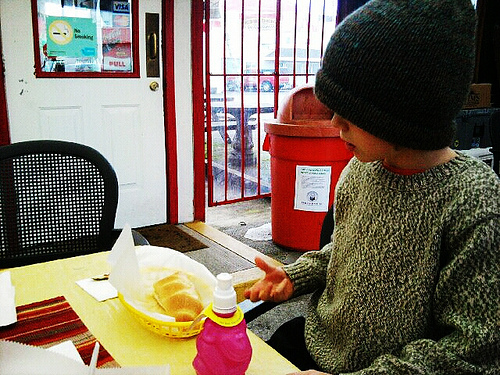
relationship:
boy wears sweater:
[281, 21, 498, 373] [282, 153, 498, 372]